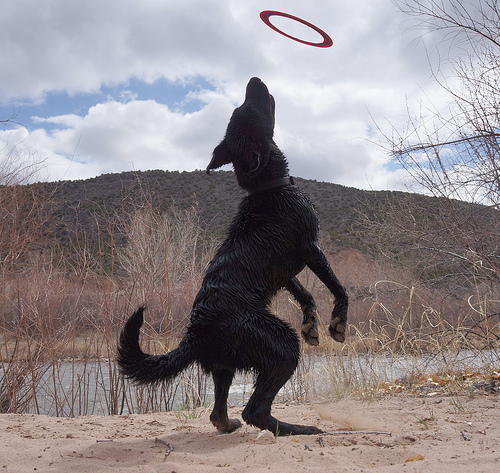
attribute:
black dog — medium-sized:
[111, 73, 345, 439]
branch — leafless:
[114, 184, 140, 213]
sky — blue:
[48, 14, 233, 185]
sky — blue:
[2, 4, 498, 210]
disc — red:
[225, 1, 365, 61]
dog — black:
[78, 59, 379, 422]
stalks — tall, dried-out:
[2, 278, 499, 414]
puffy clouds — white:
[4, 97, 389, 187]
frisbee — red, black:
[259, 10, 332, 47]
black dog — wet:
[217, 101, 289, 301]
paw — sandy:
[328, 303, 348, 341]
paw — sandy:
[299, 318, 319, 346]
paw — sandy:
[204, 412, 243, 433]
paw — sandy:
[271, 419, 326, 438]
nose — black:
[244, 74, 262, 88]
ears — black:
[208, 140, 268, 180]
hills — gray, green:
[2, 167, 498, 335]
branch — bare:
[355, 94, 498, 196]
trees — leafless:
[2, 152, 226, 414]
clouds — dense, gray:
[5, 3, 495, 209]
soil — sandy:
[0, 366, 495, 470]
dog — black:
[109, 74, 351, 434]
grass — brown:
[0, 213, 495, 421]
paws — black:
[299, 293, 348, 345]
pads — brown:
[300, 317, 344, 345]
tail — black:
[112, 301, 188, 383]